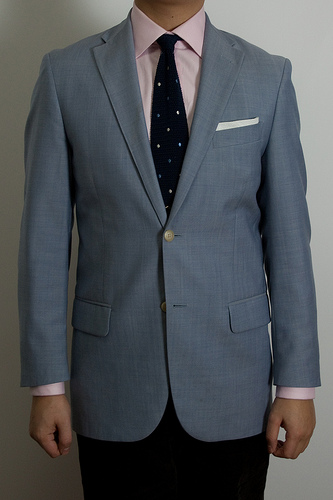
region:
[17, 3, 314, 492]
The man is wearing a suit.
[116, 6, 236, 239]
The shirt is pink.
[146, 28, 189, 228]
The tie is black with polk dots.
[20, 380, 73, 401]
A pink cuff on the shirt.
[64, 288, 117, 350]
A pocket on the jacket.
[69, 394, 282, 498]
The pants are black.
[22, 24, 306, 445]
The suit jacket is grey.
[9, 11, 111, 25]
The wall is white.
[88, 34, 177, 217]
The lapel on the suit.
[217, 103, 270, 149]
A hankerchief in the suit pocket.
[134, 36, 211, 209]
A black necktie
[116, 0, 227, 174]
A tie around the man's neck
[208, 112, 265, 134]
A white handkerchief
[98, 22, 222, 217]
The jacket's lapel is blue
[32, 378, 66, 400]
Pink sleeves peeking out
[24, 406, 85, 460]
A closed fist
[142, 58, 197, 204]
Small dots on the tie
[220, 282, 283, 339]
A suit pocket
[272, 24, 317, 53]
A blank white background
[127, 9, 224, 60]
A pink shirt collar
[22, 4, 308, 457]
The suit jacket is grey.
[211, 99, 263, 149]
A hankerchief folded in the suit pocket.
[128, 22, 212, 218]
A black tie with polka dots.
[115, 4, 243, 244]
The shirt is pink.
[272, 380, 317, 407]
The shirt cuff is pink.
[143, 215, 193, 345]
Two buttons on the suit.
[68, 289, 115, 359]
A pocket on the suit jacket.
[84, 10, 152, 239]
The lapel on the suit.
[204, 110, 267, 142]
white handkerchief in jacket pocket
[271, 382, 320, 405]
pink shirt cuff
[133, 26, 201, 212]
blue polka dot tie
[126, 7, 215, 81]
pink button down shirt with blue tie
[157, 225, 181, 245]
button on suit jacket buttoned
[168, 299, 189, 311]
button hold on blue grey suit jacket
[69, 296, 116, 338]
folded flap of pocket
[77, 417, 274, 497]
person wearing black pants with suit jacket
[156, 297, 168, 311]
undone button on suit jacket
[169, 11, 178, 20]
freckle on neck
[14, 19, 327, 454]
a gray suit with pockets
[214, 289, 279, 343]
pocket on right side of suit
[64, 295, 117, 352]
pocket on left side of suit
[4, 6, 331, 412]
a pink shirt under suit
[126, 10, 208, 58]
pink collar of shirt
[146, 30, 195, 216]
a black tie over a pink shirt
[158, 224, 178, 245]
a button color beige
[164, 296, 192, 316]
buttonhole of suit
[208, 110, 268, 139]
white handkerchief on pocket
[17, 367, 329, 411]
pink cuffs stick out of suit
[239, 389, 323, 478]
hand of the man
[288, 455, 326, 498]
wall behind the man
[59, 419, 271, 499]
black pants on man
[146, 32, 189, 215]
The blue tie on the man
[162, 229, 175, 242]
The button on the jacket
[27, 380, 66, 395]
The pink sleeve on the wrist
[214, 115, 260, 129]
The white cloth in the breastpocket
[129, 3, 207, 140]
The pink shirt under the tie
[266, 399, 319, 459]
The hand of the man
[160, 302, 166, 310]
The button covered by the jacket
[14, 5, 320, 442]
The grey jacket on the man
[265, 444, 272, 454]
The thumbnail on the man